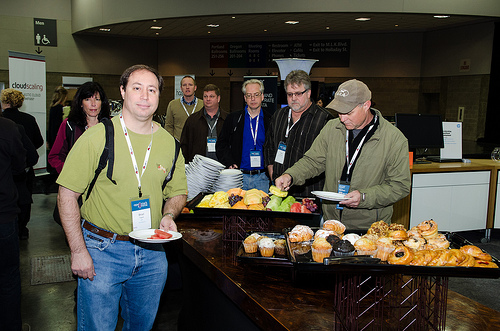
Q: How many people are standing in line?
A: Seven.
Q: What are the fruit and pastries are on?
A: Trays.